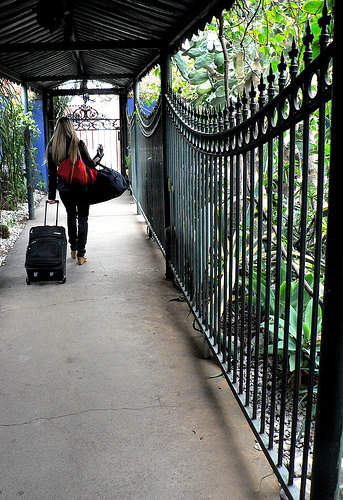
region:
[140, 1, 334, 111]
green leaves of trees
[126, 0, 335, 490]
black poles of fence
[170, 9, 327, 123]
decorative top of fence poles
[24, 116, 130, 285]
woman walking with luggage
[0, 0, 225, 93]
roof over cement walkway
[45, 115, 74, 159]
long hair on woman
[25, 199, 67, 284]
black luggage with handle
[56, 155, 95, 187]
red bag on back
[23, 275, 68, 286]
wheels on bottom of luggage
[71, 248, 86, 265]
shoes with tall heels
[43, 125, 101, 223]
this is a lady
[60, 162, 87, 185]
this is a bag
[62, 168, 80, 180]
the bag is red in color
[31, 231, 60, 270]
the bag is black in color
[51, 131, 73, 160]
this is the hair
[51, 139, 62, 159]
the hair is long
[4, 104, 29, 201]
this is a tree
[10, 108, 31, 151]
the leaves are green in color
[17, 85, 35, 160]
this is a pole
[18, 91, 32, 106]
the pole is blue in color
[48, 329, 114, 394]
this is the floor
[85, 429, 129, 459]
the floor is clean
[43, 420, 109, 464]
the floor is grey in color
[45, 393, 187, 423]
this is a crack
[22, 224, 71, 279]
this is a suitcase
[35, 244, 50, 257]
the suitcase is black in color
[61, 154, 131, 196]
these are some bags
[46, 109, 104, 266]
this is a woman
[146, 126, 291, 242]
this is a grill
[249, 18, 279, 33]
the leaves are green in color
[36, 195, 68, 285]
girl carrying black luggage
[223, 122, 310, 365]
greens behind black gate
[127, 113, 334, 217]
long black gated area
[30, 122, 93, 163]
girl with long blonde hair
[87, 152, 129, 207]
duffel bag carried on right arm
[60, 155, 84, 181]
red back pack on the back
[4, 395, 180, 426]
crack in the sidewalk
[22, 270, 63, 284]
luggage has wheels on bottom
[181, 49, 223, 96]
leaves overhang on fence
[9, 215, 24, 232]
stones on the ground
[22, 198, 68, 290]
black luggage on wheels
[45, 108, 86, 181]
woman with long blonde hair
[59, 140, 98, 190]
red duffel bag around women's shoulder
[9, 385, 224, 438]
crack in the sidewalk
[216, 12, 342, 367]
black wrought iron gate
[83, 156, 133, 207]
black duffel bag on woman's arm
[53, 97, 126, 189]
black wrought iron gate at the end of the pathway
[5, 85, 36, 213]
trees lining pathway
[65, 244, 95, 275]
woman wearing wedge heels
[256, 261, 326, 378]
small green plants